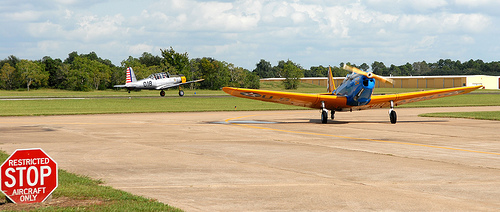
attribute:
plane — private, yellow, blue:
[219, 63, 486, 124]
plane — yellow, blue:
[223, 53, 493, 145]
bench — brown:
[395, 172, 406, 185]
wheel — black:
[313, 106, 333, 123]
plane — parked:
[108, 59, 203, 97]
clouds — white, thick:
[0, 0, 499, 67]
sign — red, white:
[0, 149, 62, 209]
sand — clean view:
[143, 127, 302, 184]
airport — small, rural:
[1, 55, 484, 206]